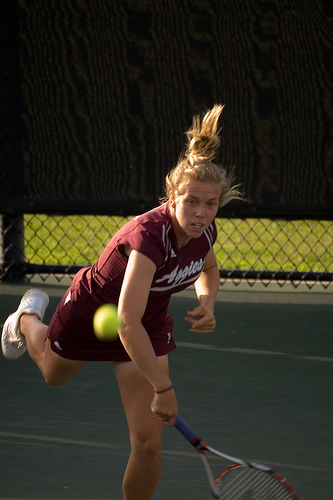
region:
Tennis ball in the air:
[68, 297, 143, 368]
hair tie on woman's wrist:
[130, 367, 193, 436]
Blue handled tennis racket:
[161, 408, 298, 494]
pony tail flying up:
[161, 89, 241, 188]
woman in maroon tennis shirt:
[104, 174, 247, 315]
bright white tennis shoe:
[4, 272, 49, 384]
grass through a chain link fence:
[255, 197, 330, 304]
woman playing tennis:
[97, 148, 263, 499]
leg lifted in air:
[3, 285, 84, 402]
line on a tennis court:
[236, 325, 320, 397]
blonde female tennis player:
[6, 136, 297, 495]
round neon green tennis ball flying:
[94, 303, 124, 333]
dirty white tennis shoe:
[0, 289, 49, 357]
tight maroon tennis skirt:
[48, 272, 176, 357]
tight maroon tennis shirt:
[88, 206, 212, 313]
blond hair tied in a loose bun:
[161, 114, 240, 208]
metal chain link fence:
[2, 212, 328, 287]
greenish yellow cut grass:
[21, 212, 329, 289]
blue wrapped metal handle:
[167, 409, 205, 456]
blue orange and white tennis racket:
[170, 405, 298, 499]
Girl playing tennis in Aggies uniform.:
[0, 99, 283, 408]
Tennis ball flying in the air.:
[84, 294, 129, 336]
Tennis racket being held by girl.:
[150, 370, 290, 493]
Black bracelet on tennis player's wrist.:
[147, 383, 182, 396]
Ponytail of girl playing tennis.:
[172, 106, 235, 170]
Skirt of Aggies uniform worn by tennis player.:
[63, 272, 171, 348]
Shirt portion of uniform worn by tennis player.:
[93, 196, 214, 290]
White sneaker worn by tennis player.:
[0, 283, 48, 352]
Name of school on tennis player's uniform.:
[149, 255, 205, 285]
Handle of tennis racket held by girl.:
[150, 400, 205, 452]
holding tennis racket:
[143, 372, 325, 496]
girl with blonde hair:
[155, 101, 257, 250]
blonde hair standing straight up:
[163, 102, 240, 236]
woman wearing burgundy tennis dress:
[44, 95, 229, 400]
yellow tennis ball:
[84, 290, 132, 346]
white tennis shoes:
[0, 281, 46, 371]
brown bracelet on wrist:
[143, 381, 187, 426]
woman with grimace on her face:
[155, 151, 246, 250]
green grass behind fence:
[249, 223, 322, 259]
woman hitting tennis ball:
[36, 116, 305, 497]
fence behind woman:
[3, 122, 329, 293]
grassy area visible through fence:
[11, 207, 329, 288]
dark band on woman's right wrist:
[144, 368, 183, 408]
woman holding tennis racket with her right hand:
[158, 398, 302, 495]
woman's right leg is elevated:
[20, 308, 82, 388]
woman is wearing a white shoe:
[0, 286, 50, 360]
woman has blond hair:
[163, 92, 253, 207]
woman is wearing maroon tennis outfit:
[42, 198, 214, 356]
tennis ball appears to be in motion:
[87, 298, 129, 344]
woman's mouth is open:
[181, 218, 210, 234]